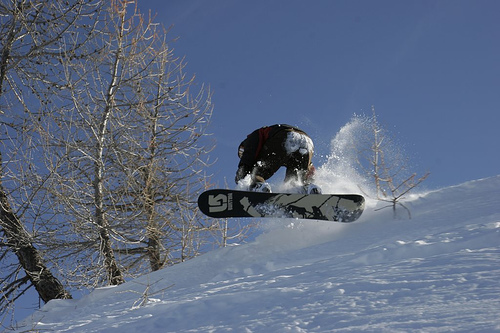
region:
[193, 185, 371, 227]
a black and white snowboard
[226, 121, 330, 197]
a person on a snowboard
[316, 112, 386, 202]
white powder in the air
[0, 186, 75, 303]
the trunk of a tree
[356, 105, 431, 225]
branches of a tree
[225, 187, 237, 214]
writing on the snowboard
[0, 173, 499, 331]
white snow on the ground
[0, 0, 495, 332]
a clear blue sky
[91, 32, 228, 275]
an barren tree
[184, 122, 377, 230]
a person snowboarding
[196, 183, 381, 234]
black and white snowboard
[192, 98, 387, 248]
the snow is blowing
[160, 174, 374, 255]
the snowboard is white and black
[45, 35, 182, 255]
the trees are bare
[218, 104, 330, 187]
the snowboarder is jumping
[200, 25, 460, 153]
the sky is clear and blue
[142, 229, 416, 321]
the sun is on the snow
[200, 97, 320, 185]
the snowboarder is wearing black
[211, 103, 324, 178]
the snow is on the snowboarders butt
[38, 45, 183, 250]
the trees are grey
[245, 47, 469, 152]
there are no clouds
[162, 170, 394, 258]
black and white snowboard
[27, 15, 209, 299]
brown skinny trees in the snow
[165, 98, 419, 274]
a snowboarder doing a trick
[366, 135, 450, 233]
small brown branches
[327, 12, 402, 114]
dark blue sky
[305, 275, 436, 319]
white snow with tracks in it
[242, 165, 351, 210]
snowboard boots on the snowboard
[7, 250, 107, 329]
thick brown tree trunk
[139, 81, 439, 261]
a snowboarder in mid air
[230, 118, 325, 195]
a person on the snowboard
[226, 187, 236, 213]
white writing on the snowboard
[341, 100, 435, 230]
the branches of a tree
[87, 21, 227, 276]
a barren tree